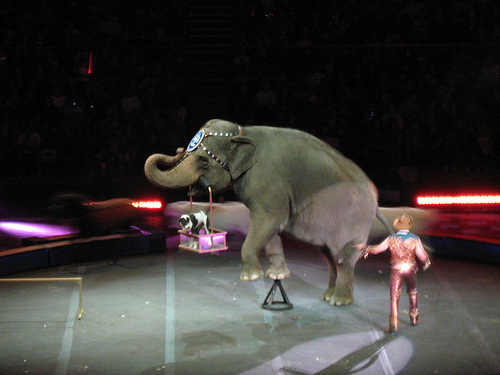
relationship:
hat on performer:
[391, 213, 415, 231] [352, 213, 433, 335]